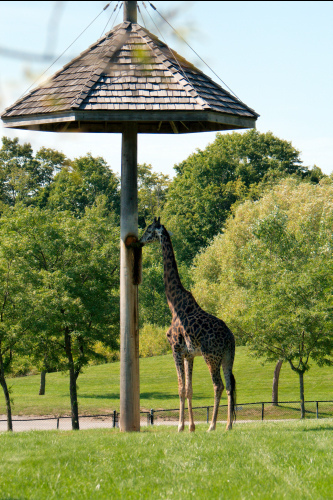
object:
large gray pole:
[119, 132, 140, 432]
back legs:
[222, 355, 235, 423]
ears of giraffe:
[154, 216, 161, 222]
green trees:
[195, 134, 287, 195]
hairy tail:
[227, 369, 237, 422]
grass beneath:
[160, 422, 267, 471]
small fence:
[0, 397, 333, 435]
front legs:
[184, 359, 194, 424]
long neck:
[158, 235, 187, 293]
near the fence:
[191, 173, 332, 420]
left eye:
[147, 228, 152, 233]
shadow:
[62, 391, 208, 402]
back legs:
[208, 364, 225, 422]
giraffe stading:
[133, 216, 237, 433]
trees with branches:
[164, 121, 305, 249]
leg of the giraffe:
[171, 350, 234, 433]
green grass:
[178, 447, 250, 489]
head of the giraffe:
[135, 215, 164, 249]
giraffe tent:
[0, 20, 259, 136]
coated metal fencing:
[3, 395, 330, 422]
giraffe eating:
[134, 212, 176, 260]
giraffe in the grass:
[135, 215, 237, 432]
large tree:
[186, 174, 333, 416]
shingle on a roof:
[119, 48, 148, 70]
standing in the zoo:
[137, 215, 239, 435]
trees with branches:
[18, 215, 98, 343]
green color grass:
[74, 428, 156, 480]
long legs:
[173, 350, 186, 420]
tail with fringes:
[189, 316, 216, 343]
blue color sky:
[225, 18, 331, 89]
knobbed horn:
[158, 216, 160, 222]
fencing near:
[10, 393, 329, 427]